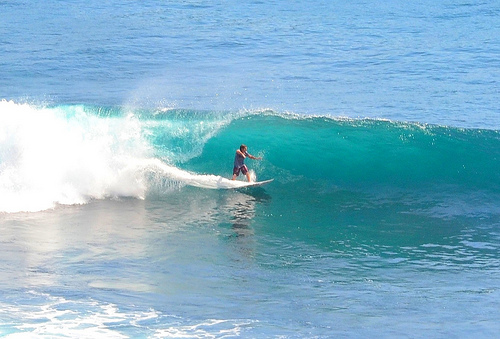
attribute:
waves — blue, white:
[13, 92, 110, 185]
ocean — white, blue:
[5, 42, 471, 326]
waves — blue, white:
[319, 101, 444, 204]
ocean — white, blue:
[41, 39, 422, 329]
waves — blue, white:
[13, 87, 155, 215]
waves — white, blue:
[324, 111, 426, 238]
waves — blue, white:
[37, 106, 149, 212]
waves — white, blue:
[9, 77, 78, 169]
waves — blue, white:
[84, 58, 290, 137]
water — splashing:
[22, 79, 132, 212]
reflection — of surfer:
[214, 186, 291, 265]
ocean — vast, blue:
[11, 30, 487, 336]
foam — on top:
[23, 274, 151, 331]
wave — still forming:
[209, 73, 489, 233]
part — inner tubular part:
[149, 112, 246, 175]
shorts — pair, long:
[233, 162, 247, 174]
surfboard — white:
[225, 177, 275, 187]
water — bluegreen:
[2, 0, 498, 336]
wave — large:
[4, 96, 498, 216]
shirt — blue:
[236, 151, 248, 166]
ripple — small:
[214, 38, 248, 48]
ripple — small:
[183, 42, 222, 51]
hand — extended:
[258, 155, 265, 159]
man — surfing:
[230, 143, 262, 182]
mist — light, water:
[122, 57, 171, 114]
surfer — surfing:
[233, 143, 257, 182]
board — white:
[183, 176, 274, 190]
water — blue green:
[138, 117, 488, 251]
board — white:
[200, 179, 275, 195]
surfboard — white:
[221, 177, 275, 193]